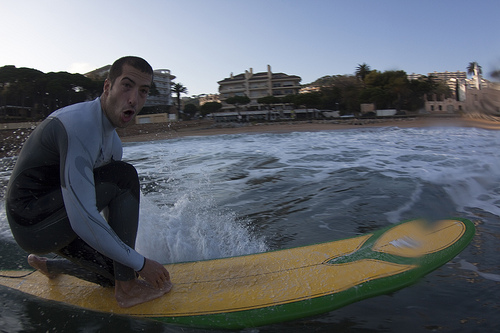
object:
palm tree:
[354, 61, 371, 84]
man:
[4, 55, 173, 309]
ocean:
[0, 126, 500, 333]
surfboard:
[0, 215, 476, 333]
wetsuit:
[4, 97, 147, 291]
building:
[215, 64, 302, 112]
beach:
[0, 111, 500, 159]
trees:
[330, 75, 362, 114]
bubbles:
[178, 187, 228, 225]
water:
[173, 264, 278, 308]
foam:
[261, 140, 490, 176]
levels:
[218, 86, 300, 93]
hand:
[137, 257, 171, 290]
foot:
[113, 278, 174, 309]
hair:
[107, 56, 153, 82]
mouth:
[121, 107, 137, 123]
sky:
[0, 2, 500, 98]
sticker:
[389, 233, 422, 253]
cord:
[0, 254, 60, 281]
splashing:
[136, 170, 282, 263]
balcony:
[220, 87, 246, 94]